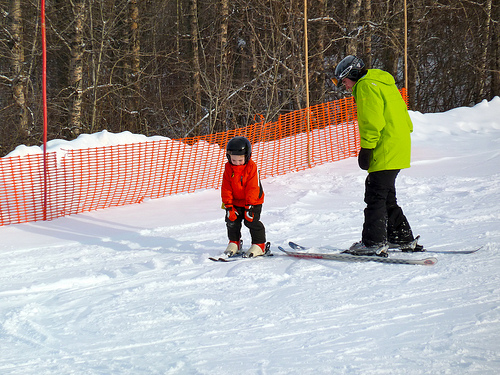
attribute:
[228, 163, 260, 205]
sweater — orange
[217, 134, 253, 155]
helmet — black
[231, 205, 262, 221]
glove — orange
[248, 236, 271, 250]
boot — white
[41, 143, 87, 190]
net — orange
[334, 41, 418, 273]
adult — standing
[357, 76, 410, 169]
jacket — yellow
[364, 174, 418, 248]
pants — black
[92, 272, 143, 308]
snow — white, whtie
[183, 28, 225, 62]
tree — brown